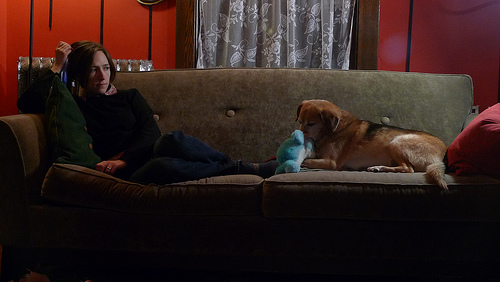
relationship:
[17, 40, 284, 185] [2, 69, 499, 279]
woman on couch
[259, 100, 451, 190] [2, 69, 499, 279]
dog laying on couch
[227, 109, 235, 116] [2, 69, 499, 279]
button on couch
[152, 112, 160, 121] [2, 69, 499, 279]
button on couch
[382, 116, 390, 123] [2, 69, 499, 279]
button on couch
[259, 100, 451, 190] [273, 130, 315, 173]
dog with toy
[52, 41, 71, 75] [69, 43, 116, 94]
right hand on womans head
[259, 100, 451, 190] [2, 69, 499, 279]
dog on couch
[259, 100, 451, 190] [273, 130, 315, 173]
dog playing with toy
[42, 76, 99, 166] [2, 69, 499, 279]
green pillow on couch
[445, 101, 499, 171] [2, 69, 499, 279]
red pillow on couch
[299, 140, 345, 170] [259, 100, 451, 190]
leg of dog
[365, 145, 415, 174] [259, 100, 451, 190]
leg of dog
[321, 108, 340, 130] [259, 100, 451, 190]
ear of dog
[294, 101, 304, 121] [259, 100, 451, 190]
ear of dog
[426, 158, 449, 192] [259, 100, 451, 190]
tail of dog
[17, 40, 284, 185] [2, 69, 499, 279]
woman leaning on couch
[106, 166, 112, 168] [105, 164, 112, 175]
ring on her finger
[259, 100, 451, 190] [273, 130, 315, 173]
dog has toy